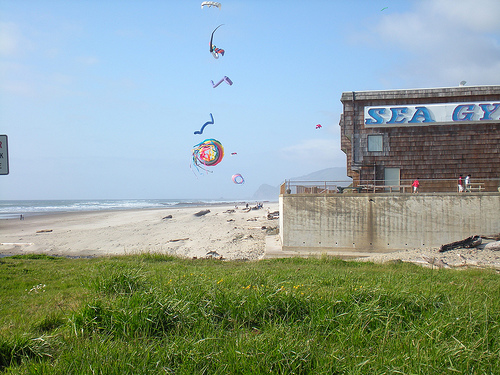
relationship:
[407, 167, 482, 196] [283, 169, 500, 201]
people are on motel deck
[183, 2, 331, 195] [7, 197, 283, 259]
kites flying above beach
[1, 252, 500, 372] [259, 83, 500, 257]
grassy strip next to beach motel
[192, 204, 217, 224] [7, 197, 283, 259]
driftwood on beach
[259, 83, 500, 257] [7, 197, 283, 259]
motel right on beach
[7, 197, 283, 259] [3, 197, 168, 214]
beach has breaking waves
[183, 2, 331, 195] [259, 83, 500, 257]
kites behind motel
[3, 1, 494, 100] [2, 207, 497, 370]
sky above land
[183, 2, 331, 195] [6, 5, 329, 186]
kites in air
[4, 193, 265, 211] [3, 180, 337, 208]
ocean in distance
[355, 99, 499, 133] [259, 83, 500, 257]
sign on building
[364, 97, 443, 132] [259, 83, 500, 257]
word sea on side building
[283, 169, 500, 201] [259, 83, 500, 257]
fence around building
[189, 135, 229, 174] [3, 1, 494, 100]
kite in sky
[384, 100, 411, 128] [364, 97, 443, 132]
letter e in sea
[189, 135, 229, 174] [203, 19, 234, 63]
kite in sky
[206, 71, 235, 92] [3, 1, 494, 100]
kite in sky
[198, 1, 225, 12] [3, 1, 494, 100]
kite in sky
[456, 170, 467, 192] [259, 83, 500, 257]
person near a building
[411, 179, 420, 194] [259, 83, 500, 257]
people near building